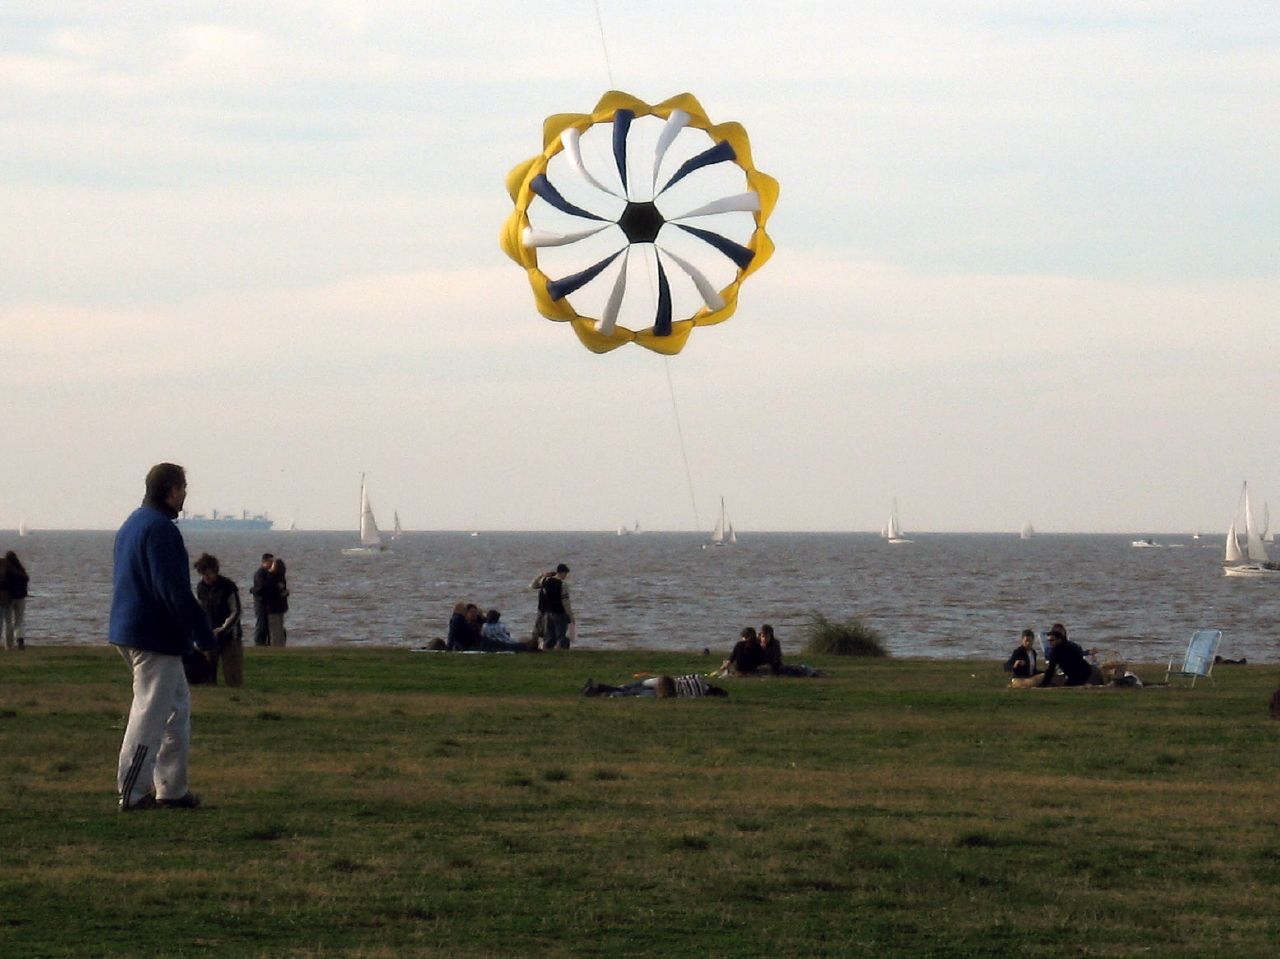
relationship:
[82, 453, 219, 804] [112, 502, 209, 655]
man wearing coat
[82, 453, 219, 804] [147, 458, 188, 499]
man has hair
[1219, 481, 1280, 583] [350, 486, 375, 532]
boat on boat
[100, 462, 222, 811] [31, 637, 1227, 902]
man walking grass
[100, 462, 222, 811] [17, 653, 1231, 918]
man kneeling grass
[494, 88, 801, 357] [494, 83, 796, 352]
kite has border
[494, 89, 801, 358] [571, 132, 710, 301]
kite has blades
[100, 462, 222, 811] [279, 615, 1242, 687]
man near shore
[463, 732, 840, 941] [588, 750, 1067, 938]
view of ground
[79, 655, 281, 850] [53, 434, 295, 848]
legs of person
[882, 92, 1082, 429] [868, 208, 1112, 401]
view of clouds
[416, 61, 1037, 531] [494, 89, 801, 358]
view of kite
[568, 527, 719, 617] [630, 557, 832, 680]
view of water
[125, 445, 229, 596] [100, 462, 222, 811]
face of man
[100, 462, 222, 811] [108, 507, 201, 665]
man wearing coat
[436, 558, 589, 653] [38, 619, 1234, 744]
people on shore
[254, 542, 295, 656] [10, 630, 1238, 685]
couple embracing on shore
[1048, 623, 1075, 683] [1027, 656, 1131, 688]
woman sitting on chair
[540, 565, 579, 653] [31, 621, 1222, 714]
couple walking along shore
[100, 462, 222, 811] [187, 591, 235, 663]
man carrying bag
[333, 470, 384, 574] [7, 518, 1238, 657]
boat on water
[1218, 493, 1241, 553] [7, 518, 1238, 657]
boat on water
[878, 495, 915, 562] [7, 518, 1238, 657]
boat on water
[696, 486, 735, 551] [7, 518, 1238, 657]
boat on water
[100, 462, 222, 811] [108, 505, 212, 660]
man wearing coat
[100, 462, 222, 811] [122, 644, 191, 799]
man wearing pants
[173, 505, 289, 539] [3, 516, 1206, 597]
ship on horizon